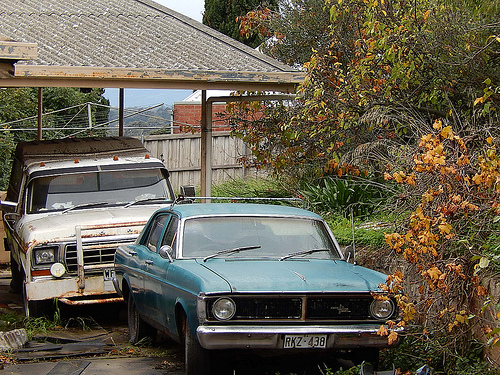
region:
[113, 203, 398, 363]
Front car is blue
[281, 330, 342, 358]
License plate on blue car is RKZ-438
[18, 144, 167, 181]
White truck has 4 orange lights on top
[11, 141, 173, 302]
White truck is parked under outside garage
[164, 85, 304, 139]
Brick building behind fence in background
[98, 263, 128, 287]
First 2 letters showing on truck license is WF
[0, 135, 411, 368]
Both white truck and blue car are not new vehicles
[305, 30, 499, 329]
Trees leaves are both green and yellow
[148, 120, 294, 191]
Back fence is made out of wood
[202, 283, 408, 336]
Blue car has 2 headlights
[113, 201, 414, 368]
Blue Chevy Nova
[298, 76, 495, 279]
Overgrown vegetation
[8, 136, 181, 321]
An older white truck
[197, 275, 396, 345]
the front grill is damaged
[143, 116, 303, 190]
A grey fence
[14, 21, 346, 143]
A grey carport roof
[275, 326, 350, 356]
A white license plate reading RKZ438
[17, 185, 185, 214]
A few pieces of garbage on the truck dashboard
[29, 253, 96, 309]
A covered fog lamp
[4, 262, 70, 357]
The trucks tires are flat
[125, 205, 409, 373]
blue car in foreground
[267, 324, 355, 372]
white license plate with black lettering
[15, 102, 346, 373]
two vehicles in photo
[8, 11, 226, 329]
one vehicle under carport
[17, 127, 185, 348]
one white vehicle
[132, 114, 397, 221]
wooden fence in photograph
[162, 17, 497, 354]
trees with dying leaves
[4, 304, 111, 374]
trash laying on ground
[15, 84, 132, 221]
green tree in background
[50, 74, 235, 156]
red house in background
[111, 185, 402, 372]
A pale blue old car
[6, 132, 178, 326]
A white and rusty old truck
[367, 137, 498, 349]
Yellow and orange leaves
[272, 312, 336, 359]
An old license plate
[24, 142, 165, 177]
4 orange lights on the truck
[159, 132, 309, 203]
A wooden privacy fence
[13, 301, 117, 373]
Debris or trash on the ground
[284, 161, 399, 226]
A pointy leave plant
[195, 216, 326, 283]
A set of windshield wipers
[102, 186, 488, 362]
A sedan style car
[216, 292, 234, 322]
The light of a vehicle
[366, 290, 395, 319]
The light of a vehicle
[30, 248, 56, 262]
The light of a vehicle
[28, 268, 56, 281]
The light of a vehicle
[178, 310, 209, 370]
The tire of a vehicle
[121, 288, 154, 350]
The tire of a vehicle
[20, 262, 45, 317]
The tire of a vehicle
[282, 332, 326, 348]
The number plate of a vehicle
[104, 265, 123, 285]
The number plate of a vehicle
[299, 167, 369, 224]
a green tree